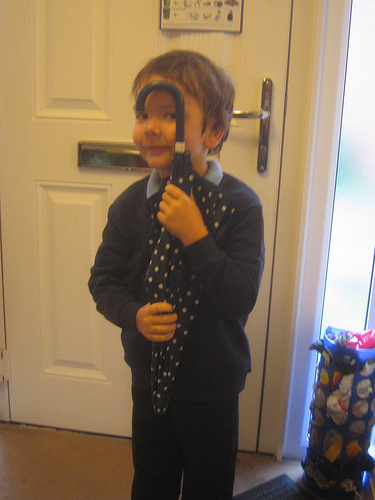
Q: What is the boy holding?
A: An umbrella.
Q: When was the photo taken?
A: Day time.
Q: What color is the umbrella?
A: Blue.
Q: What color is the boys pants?
A: Black.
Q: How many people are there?
A: One.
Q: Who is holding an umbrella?
A: A boy.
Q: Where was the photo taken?
A: By the front door.